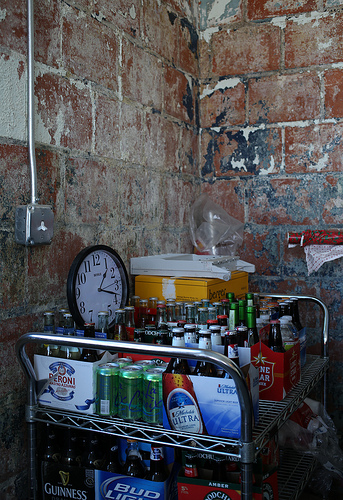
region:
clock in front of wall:
[51, 230, 142, 324]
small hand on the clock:
[93, 263, 116, 286]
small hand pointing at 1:
[94, 266, 112, 287]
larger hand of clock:
[92, 284, 122, 303]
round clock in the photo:
[66, 237, 137, 326]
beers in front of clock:
[88, 293, 287, 384]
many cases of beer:
[122, 283, 301, 400]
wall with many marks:
[261, 91, 320, 184]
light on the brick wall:
[16, 199, 69, 256]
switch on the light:
[34, 217, 52, 237]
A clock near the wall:
[67, 240, 131, 328]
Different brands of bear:
[5, 295, 337, 490]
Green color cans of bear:
[97, 354, 166, 427]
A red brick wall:
[61, 12, 294, 201]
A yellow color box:
[127, 262, 250, 296]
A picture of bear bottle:
[159, 371, 247, 433]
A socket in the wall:
[6, 201, 62, 246]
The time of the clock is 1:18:
[68, 234, 129, 331]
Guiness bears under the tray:
[34, 472, 96, 498]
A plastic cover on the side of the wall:
[181, 185, 237, 245]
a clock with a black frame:
[51, 249, 139, 334]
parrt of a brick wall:
[29, 7, 341, 211]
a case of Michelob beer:
[157, 345, 262, 443]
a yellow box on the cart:
[133, 273, 326, 318]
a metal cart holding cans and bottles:
[30, 284, 327, 497]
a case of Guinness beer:
[37, 427, 93, 495]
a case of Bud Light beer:
[95, 434, 169, 495]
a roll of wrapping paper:
[271, 221, 338, 266]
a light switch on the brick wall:
[21, 200, 53, 243]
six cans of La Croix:
[100, 360, 185, 443]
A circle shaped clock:
[65, 240, 130, 336]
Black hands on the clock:
[90, 265, 120, 304]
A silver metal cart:
[10, 287, 332, 496]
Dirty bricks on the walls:
[2, 0, 338, 497]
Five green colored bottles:
[225, 284, 258, 333]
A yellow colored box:
[130, 267, 250, 308]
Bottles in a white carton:
[30, 306, 122, 419]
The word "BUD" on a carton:
[112, 476, 160, 498]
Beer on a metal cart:
[11, 285, 331, 497]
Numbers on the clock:
[72, 252, 122, 326]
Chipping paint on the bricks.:
[34, 78, 93, 152]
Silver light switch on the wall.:
[10, 199, 60, 258]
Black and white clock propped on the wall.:
[64, 235, 135, 332]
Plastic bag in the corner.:
[178, 190, 244, 255]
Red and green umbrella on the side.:
[276, 223, 339, 254]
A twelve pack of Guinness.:
[27, 435, 104, 499]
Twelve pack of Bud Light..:
[74, 443, 172, 499]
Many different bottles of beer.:
[132, 295, 255, 328]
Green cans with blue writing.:
[89, 355, 167, 419]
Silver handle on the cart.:
[0, 333, 234, 350]